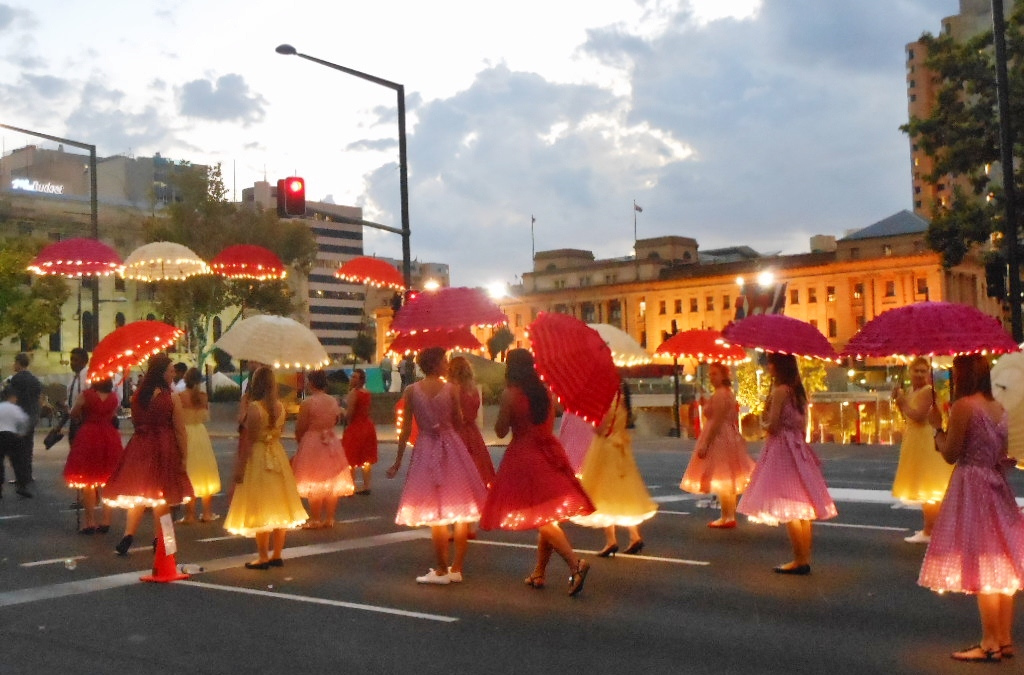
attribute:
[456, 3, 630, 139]
sky — cloudy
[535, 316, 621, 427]
umbrella — red, white, pink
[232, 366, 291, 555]
girl — around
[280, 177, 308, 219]
light — red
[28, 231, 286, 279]
umbrellas — lit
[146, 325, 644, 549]
people — watching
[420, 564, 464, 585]
shoes — white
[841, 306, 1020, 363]
umbrella — pink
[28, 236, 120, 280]
umbrella — pink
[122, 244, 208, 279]
umbrella — white